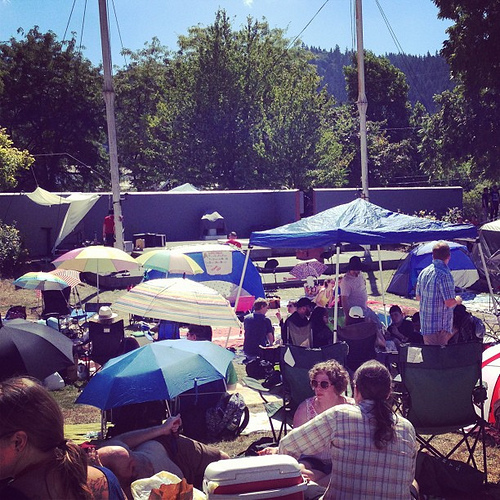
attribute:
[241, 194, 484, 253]
canopy — blue, dark blue, small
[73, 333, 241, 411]
umbrella — blue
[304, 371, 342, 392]
sunglasses — dark, large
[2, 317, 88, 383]
umbrella — black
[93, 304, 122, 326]
hat — white, straw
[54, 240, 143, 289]
umbrella — multicolored, rainbow colored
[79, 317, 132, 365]
folding chair — black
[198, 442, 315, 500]
cooler — white, red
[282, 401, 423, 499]
shirt — checkered, plaid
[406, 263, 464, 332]
shirt — white, blue, plaid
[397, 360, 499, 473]
chair — canvas, green, dark green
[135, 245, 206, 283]
umbrella — orange, green, yellow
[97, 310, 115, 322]
stripe — brown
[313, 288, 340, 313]
shirt — yellow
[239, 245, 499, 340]
poles — metal, white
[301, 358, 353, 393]
hair — curly, short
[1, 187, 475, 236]
wall — grey, brick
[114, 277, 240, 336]
umbrella — striped, multicolored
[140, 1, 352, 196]
tree — green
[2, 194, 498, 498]
people — gathering